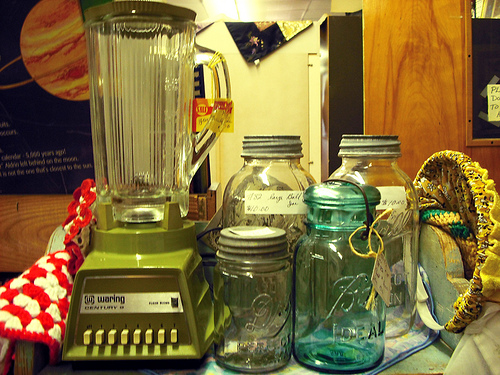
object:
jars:
[324, 134, 418, 337]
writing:
[319, 272, 361, 321]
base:
[60, 199, 234, 361]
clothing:
[0, 181, 79, 359]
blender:
[59, 1, 236, 361]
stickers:
[242, 188, 310, 216]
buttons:
[80, 327, 92, 347]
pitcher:
[78, 2, 233, 224]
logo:
[83, 293, 126, 312]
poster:
[3, 2, 212, 194]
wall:
[213, 32, 309, 141]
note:
[486, 82, 500, 125]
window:
[465, 17, 500, 143]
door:
[358, 0, 499, 203]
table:
[48, 334, 498, 375]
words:
[163, 75, 180, 94]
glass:
[210, 224, 291, 374]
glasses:
[297, 179, 387, 375]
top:
[337, 133, 403, 159]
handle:
[194, 43, 237, 175]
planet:
[21, 0, 92, 104]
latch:
[239, 134, 304, 161]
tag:
[193, 96, 237, 134]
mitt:
[2, 178, 91, 369]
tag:
[368, 185, 408, 211]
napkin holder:
[418, 146, 496, 375]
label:
[79, 291, 185, 314]